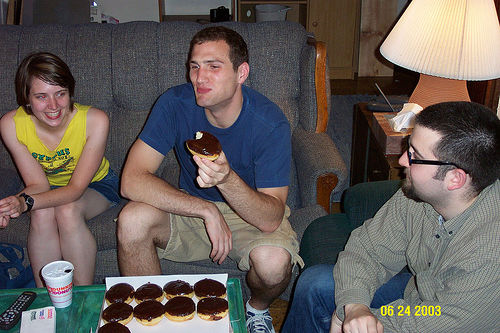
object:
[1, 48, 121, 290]
woman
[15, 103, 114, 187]
tanktop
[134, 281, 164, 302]
donut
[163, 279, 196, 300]
donut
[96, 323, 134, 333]
donut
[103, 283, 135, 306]
donut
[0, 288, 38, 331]
remote control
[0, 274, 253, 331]
table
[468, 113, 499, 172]
hair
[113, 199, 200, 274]
right leg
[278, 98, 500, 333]
seated man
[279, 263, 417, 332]
blue jeans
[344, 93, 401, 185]
table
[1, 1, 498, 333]
living room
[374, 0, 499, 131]
lamp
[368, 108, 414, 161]
tissue box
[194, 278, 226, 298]
chocolate donut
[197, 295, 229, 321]
chocolate donut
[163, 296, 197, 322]
chocolate donut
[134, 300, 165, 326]
chocolate donut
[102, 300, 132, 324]
chocolate donut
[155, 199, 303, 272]
khaki shorts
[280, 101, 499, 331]
man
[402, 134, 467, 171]
eyeglasses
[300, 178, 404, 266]
chair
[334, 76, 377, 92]
floor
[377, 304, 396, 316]
date stamp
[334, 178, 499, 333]
shirt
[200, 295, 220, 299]
frosting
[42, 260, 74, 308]
cup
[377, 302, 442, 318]
date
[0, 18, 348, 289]
sofa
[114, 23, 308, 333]
man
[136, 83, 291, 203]
t-shirt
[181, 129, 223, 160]
donut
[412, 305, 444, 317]
stamp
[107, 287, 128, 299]
chocolate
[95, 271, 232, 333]
box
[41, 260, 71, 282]
dunkin donuts